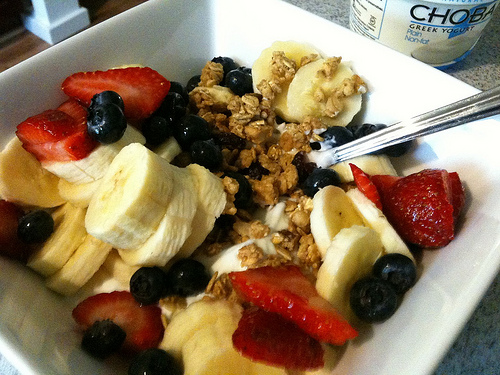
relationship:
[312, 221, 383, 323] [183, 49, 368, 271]
banana with granola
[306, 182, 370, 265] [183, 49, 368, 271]
banana with granola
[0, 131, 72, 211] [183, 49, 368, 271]
banana with granola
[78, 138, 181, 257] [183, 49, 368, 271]
banana with granola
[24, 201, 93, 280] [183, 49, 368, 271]
banana with granola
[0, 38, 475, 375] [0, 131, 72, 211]
fruit plate with banana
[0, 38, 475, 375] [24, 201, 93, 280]
fruit plate with banana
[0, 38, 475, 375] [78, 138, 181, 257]
fruit plate with banana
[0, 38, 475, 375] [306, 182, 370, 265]
fruit plate with banana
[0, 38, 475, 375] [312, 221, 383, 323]
fruit plate with banana